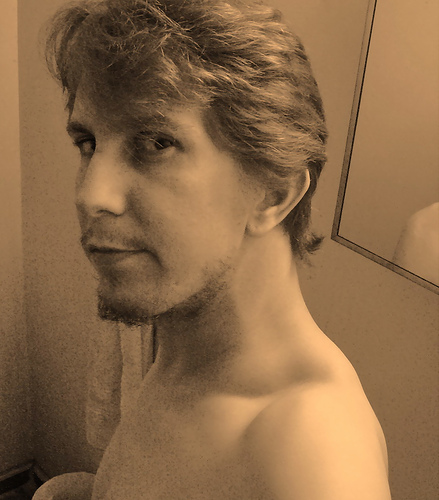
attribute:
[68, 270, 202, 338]
hair — feathered, facial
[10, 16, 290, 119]
hair — wavy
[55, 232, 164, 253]
mustach — thin